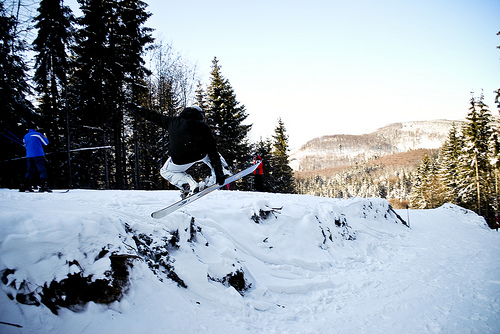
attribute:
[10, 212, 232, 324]
rock — snow covered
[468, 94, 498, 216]
trees — green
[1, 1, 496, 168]
sky — blue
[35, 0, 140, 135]
trees — green, sunlit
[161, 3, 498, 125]
sky — blue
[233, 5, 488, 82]
sky — blue, cold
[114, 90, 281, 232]
person — athletic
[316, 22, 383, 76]
sky — blue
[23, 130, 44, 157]
jacket — blue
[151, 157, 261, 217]
snow board — white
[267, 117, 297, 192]
evergreen — tall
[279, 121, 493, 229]
hill — far, snowy, distant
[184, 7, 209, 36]
clouds — white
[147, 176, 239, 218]
board — white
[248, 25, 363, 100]
clouds — white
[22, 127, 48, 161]
jacket — blue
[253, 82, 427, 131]
clouds — white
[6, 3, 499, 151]
sky — blue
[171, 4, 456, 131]
cloud — white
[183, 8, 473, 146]
cloud — white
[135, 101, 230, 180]
sweater — black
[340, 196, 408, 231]
rock — snow covered